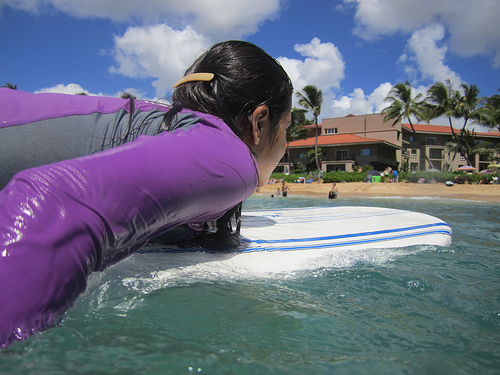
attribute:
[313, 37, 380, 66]
cloud — white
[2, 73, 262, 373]
wetsuit — grey, purple 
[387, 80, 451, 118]
tree — green, tall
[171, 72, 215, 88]
hair clip — brown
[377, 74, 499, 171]
trees — palm 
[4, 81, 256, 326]
wetsuit — black, purple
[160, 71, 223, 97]
barrett — hair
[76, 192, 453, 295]
surfboard — white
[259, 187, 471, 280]
board — white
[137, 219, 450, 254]
stripes — blue